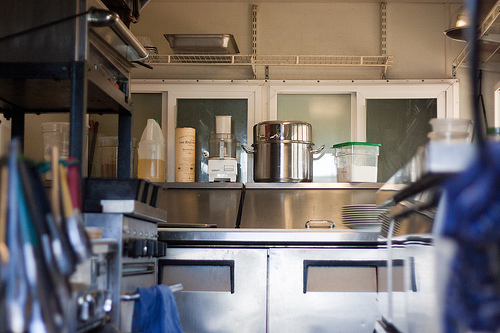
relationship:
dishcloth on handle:
[127, 285, 183, 332] [118, 280, 183, 304]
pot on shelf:
[237, 119, 326, 183] [147, 178, 407, 189]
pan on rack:
[162, 33, 242, 66] [137, 51, 394, 70]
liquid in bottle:
[137, 158, 165, 180] [137, 117, 168, 179]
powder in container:
[336, 164, 378, 183] [335, 140, 378, 181]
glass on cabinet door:
[368, 97, 437, 180] [358, 86, 448, 179]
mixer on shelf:
[203, 112, 239, 203] [92, 146, 470, 194]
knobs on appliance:
[118, 237, 166, 258] [45, 194, 193, 331]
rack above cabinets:
[137, 51, 394, 70] [68, 70, 468, 231]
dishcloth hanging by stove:
[127, 285, 183, 332] [46, 183, 202, 331]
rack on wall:
[74, 40, 488, 84] [63, 5, 492, 95]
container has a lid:
[317, 126, 393, 201] [320, 130, 395, 158]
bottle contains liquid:
[118, 108, 188, 203] [137, 159, 168, 182]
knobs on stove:
[118, 233, 176, 264] [23, 161, 199, 331]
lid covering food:
[145, 194, 438, 244] [220, 200, 448, 271]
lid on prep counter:
[145, 194, 438, 244] [117, 148, 447, 292]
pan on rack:
[162, 33, 242, 66] [35, 37, 446, 83]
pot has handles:
[239, 110, 331, 190] [227, 136, 328, 162]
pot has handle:
[237, 119, 326, 183] [298, 133, 328, 166]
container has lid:
[328, 141, 381, 184] [327, 134, 393, 153]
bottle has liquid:
[134, 117, 165, 182] [137, 159, 168, 182]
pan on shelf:
[146, 19, 247, 70] [28, 26, 498, 94]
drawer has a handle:
[226, 162, 409, 256] [282, 208, 345, 233]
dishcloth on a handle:
[108, 279, 200, 331] [112, 268, 208, 312]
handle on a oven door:
[112, 268, 208, 312] [48, 238, 194, 331]